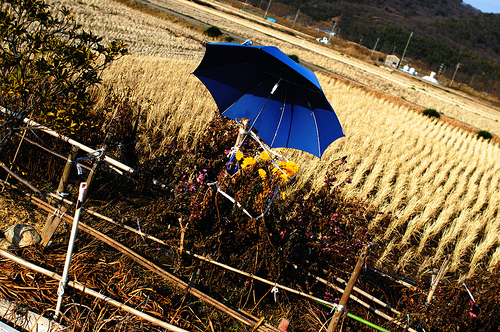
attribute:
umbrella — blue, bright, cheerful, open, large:
[186, 33, 351, 169]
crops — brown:
[343, 56, 499, 289]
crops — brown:
[53, 1, 190, 145]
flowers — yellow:
[228, 142, 297, 199]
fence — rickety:
[3, 107, 448, 331]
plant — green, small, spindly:
[0, 0, 140, 145]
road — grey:
[138, 1, 385, 83]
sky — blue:
[458, 2, 498, 22]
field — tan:
[142, 3, 495, 246]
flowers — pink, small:
[164, 128, 227, 225]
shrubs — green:
[203, 21, 236, 45]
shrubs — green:
[423, 100, 499, 147]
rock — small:
[4, 217, 44, 255]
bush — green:
[198, 19, 224, 43]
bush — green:
[420, 105, 446, 124]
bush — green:
[476, 126, 492, 145]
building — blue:
[265, 14, 279, 24]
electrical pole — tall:
[394, 30, 416, 79]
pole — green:
[311, 295, 386, 331]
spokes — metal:
[221, 76, 327, 149]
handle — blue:
[225, 151, 243, 175]